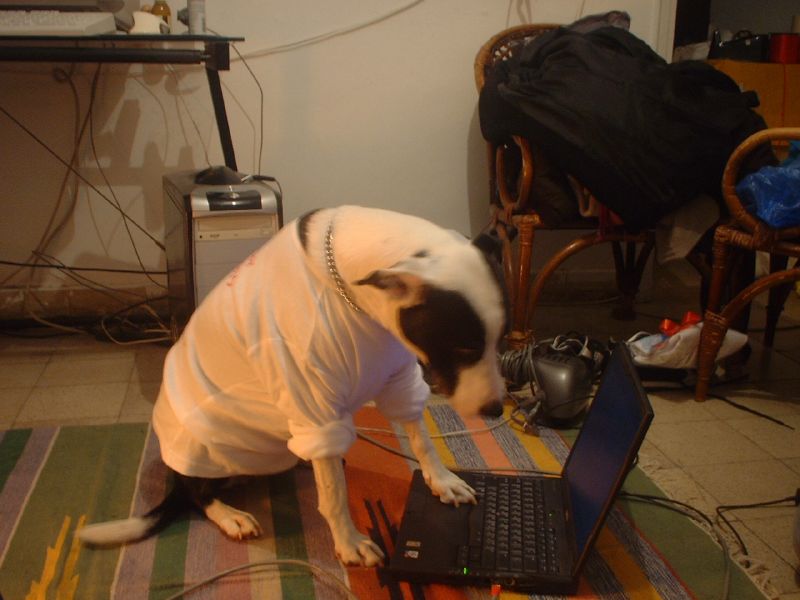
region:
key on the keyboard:
[484, 490, 513, 502]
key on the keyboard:
[517, 483, 559, 504]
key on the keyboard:
[546, 529, 555, 543]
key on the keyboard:
[497, 489, 516, 499]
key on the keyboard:
[517, 515, 535, 528]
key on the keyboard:
[536, 549, 552, 571]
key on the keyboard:
[514, 515, 530, 534]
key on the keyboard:
[486, 489, 508, 500]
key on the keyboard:
[488, 515, 501, 534]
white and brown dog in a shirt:
[125, 200, 472, 570]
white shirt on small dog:
[186, 230, 382, 462]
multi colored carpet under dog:
[2, 371, 666, 598]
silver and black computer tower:
[176, 160, 268, 357]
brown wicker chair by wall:
[459, 14, 638, 316]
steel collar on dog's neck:
[305, 200, 356, 293]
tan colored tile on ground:
[626, 370, 798, 574]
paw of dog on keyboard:
[406, 471, 478, 520]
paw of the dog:
[218, 509, 261, 530]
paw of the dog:
[338, 523, 384, 566]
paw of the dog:
[418, 457, 471, 508]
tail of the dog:
[37, 505, 131, 542]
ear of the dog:
[354, 264, 415, 296]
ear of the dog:
[472, 242, 508, 274]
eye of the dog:
[430, 336, 492, 364]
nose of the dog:
[478, 400, 503, 413]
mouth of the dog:
[419, 374, 473, 422]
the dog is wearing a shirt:
[74, 200, 507, 572]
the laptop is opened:
[387, 335, 655, 597]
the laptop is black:
[385, 338, 653, 590]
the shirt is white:
[148, 214, 431, 484]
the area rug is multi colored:
[1, 391, 781, 596]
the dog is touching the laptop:
[74, 202, 654, 598]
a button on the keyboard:
[509, 506, 541, 531]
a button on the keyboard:
[523, 499, 552, 521]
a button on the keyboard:
[521, 502, 539, 522]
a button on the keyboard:
[528, 486, 539, 492]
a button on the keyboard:
[491, 506, 525, 528]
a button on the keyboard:
[514, 552, 543, 568]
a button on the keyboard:
[491, 513, 516, 540]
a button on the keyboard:
[523, 499, 543, 519]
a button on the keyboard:
[498, 506, 525, 533]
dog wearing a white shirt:
[70, 195, 516, 561]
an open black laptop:
[377, 343, 659, 597]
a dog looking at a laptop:
[82, 200, 661, 598]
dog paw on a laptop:
[383, 338, 657, 597]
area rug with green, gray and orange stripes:
[2, 394, 778, 598]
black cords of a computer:
[3, 23, 267, 355]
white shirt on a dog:
[64, 200, 516, 574]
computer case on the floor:
[155, 169, 284, 348]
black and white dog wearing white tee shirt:
[76, 200, 513, 578]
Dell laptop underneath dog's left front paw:
[384, 334, 658, 599]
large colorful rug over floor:
[0, 385, 794, 598]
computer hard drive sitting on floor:
[157, 159, 288, 356]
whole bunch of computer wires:
[0, 26, 288, 346]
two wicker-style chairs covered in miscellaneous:
[469, 17, 799, 407]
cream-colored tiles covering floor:
[0, 330, 799, 598]